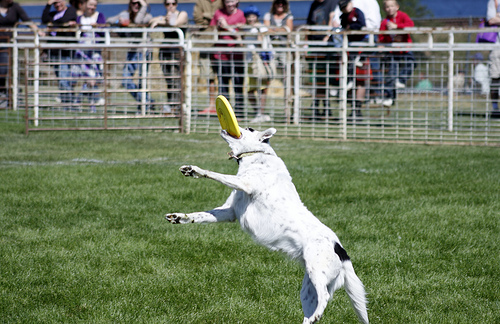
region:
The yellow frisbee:
[209, 91, 245, 147]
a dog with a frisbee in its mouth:
[149, 88, 389, 320]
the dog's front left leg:
[167, 153, 255, 194]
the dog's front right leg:
[159, 198, 230, 235]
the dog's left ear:
[260, 118, 277, 148]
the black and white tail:
[334, 240, 383, 322]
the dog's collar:
[222, 146, 283, 161]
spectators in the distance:
[32, 1, 415, 59]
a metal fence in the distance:
[305, 23, 429, 150]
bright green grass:
[20, 188, 155, 289]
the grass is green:
[44, 225, 138, 287]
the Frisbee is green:
[202, 76, 265, 158]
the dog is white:
[169, 91, 384, 316]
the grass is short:
[66, 211, 155, 292]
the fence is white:
[48, 19, 155, 129]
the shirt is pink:
[215, 0, 248, 53]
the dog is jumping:
[152, 80, 367, 321]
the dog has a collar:
[212, 128, 282, 173]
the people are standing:
[57, 0, 173, 137]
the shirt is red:
[375, 3, 411, 70]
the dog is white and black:
[178, 131, 440, 301]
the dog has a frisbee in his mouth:
[183, 86, 288, 183]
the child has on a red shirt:
[378, 2, 433, 61]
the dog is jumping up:
[141, 107, 386, 297]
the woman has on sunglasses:
[153, 0, 197, 42]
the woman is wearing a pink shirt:
[208, 2, 280, 99]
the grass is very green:
[23, 181, 153, 318]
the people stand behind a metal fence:
[163, 42, 498, 144]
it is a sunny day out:
[16, 6, 476, 313]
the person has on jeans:
[46, 39, 101, 118]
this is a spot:
[332, 220, 350, 280]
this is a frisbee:
[206, 85, 241, 140]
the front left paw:
[155, 140, 205, 185]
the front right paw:
[165, 195, 190, 240]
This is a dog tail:
[332, 241, 369, 318]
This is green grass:
[367, 165, 412, 245]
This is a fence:
[6, 15, 492, 155]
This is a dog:
[155, 83, 382, 321]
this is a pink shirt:
[198, 4, 248, 67]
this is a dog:
[258, 107, 279, 152]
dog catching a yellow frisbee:
[194, 101, 276, 149]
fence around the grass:
[38, 34, 497, 85]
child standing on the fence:
[379, 13, 433, 106]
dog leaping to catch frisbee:
[176, 93, 429, 317]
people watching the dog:
[40, 2, 460, 38]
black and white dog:
[153, 118, 404, 323]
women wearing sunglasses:
[122, 4, 196, 64]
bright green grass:
[63, 159, 173, 302]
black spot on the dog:
[326, 232, 371, 274]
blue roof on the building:
[415, 2, 480, 23]